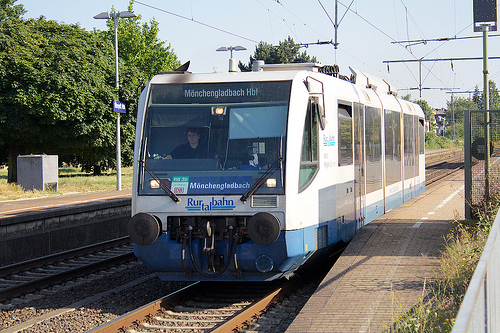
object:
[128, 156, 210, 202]
wiper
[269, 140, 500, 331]
sidewalk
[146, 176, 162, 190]
headlight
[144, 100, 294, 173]
window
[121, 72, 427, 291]
train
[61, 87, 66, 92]
leaves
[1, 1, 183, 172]
trees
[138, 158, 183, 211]
wipers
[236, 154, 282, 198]
wipers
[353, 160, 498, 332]
line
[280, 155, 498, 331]
ground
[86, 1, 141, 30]
lamps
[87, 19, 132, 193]
pole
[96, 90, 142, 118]
sign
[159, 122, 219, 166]
man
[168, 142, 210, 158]
shirt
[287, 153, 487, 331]
walkway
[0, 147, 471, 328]
train tracks